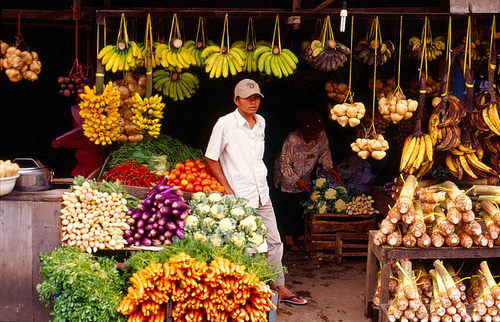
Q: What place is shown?
A: It is a market.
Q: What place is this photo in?
A: It is at the market.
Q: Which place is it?
A: It is a market.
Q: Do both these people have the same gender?
A: No, they are both male and female.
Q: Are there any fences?
A: No, there are no fences.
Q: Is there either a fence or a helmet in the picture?
A: No, there are no fences or helmets.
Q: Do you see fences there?
A: No, there are no fences.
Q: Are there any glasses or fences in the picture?
A: No, there are no fences or glasses.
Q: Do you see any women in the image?
A: Yes, there is a woman.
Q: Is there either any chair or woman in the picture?
A: Yes, there is a woman.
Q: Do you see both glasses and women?
A: No, there is a woman but no glasses.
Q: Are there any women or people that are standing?
A: Yes, the woman is standing.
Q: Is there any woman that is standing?
A: Yes, there is a woman that is standing.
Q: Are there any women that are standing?
A: Yes, there is a woman that is standing.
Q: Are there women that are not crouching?
A: Yes, there is a woman that is standing.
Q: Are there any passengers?
A: No, there are no passengers.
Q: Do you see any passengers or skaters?
A: No, there are no passengers or skaters.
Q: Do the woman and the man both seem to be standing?
A: Yes, both the woman and the man are standing.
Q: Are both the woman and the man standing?
A: Yes, both the woman and the man are standing.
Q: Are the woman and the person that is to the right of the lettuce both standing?
A: Yes, both the woman and the man are standing.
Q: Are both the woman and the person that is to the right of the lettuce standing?
A: Yes, both the woman and the man are standing.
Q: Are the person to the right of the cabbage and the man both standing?
A: Yes, both the woman and the man are standing.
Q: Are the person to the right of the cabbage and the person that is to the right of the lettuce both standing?
A: Yes, both the woman and the man are standing.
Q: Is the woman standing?
A: Yes, the woman is standing.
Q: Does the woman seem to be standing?
A: Yes, the woman is standing.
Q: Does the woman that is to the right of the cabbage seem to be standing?
A: Yes, the woman is standing.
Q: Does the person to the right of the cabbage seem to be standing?
A: Yes, the woman is standing.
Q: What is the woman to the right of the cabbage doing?
A: The woman is standing.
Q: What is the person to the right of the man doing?
A: The woman is standing.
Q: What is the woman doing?
A: The woman is standing.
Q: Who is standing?
A: The woman is standing.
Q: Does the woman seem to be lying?
A: No, the woman is standing.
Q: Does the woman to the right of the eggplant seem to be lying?
A: No, the woman is standing.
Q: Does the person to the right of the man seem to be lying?
A: No, the woman is standing.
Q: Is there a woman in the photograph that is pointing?
A: No, there is a woman but she is standing.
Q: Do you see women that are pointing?
A: No, there is a woman but she is standing.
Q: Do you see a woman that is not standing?
A: No, there is a woman but she is standing.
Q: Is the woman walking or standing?
A: The woman is standing.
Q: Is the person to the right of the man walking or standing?
A: The woman is standing.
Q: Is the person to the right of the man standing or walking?
A: The woman is standing.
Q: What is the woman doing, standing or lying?
A: The woman is standing.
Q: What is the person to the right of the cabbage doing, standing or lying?
A: The woman is standing.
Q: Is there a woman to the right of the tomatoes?
A: Yes, there is a woman to the right of the tomatoes.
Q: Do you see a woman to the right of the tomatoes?
A: Yes, there is a woman to the right of the tomatoes.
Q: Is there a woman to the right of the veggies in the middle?
A: Yes, there is a woman to the right of the tomatoes.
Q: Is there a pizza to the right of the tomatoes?
A: No, there is a woman to the right of the tomatoes.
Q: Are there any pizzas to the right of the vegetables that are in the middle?
A: No, there is a woman to the right of the tomatoes.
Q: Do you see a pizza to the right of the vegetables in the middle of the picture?
A: No, there is a woman to the right of the tomatoes.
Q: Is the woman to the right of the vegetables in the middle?
A: Yes, the woman is to the right of the tomatoes.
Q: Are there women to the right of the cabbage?
A: Yes, there is a woman to the right of the cabbage.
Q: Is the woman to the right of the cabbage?
A: Yes, the woman is to the right of the cabbage.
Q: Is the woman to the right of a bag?
A: No, the woman is to the right of the cabbage.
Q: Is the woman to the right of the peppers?
A: Yes, the woman is to the right of the peppers.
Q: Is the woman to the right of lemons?
A: No, the woman is to the right of the peppers.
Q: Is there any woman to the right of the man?
A: Yes, there is a woman to the right of the man.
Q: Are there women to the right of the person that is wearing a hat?
A: Yes, there is a woman to the right of the man.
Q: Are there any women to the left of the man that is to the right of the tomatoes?
A: No, the woman is to the right of the man.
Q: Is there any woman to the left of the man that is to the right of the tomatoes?
A: No, the woman is to the right of the man.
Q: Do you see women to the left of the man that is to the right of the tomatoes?
A: No, the woman is to the right of the man.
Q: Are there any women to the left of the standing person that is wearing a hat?
A: No, the woman is to the right of the man.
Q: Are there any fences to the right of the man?
A: No, there is a woman to the right of the man.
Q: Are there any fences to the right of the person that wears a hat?
A: No, there is a woman to the right of the man.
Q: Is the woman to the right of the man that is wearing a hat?
A: Yes, the woman is to the right of the man.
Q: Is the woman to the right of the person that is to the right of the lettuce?
A: Yes, the woman is to the right of the man.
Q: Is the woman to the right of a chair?
A: No, the woman is to the right of the man.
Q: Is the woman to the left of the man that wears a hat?
A: No, the woman is to the right of the man.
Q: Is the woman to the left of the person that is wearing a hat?
A: No, the woman is to the right of the man.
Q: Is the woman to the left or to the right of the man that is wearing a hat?
A: The woman is to the right of the man.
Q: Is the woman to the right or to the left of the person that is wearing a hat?
A: The woman is to the right of the man.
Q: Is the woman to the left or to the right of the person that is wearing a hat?
A: The woman is to the right of the man.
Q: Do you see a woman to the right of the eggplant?
A: Yes, there is a woman to the right of the eggplant.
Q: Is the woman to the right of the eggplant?
A: Yes, the woman is to the right of the eggplant.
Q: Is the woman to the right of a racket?
A: No, the woman is to the right of the eggplant.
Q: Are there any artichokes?
A: No, there are no artichokes.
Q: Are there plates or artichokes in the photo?
A: No, there are no artichokes or plates.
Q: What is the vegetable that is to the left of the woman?
A: The vegetable is a cabbage.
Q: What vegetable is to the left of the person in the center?
A: The vegetable is a cabbage.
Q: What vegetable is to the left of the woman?
A: The vegetable is a cabbage.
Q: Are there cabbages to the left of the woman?
A: Yes, there is a cabbage to the left of the woman.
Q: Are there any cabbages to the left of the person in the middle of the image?
A: Yes, there is a cabbage to the left of the woman.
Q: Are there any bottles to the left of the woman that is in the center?
A: No, there is a cabbage to the left of the woman.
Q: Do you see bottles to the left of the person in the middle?
A: No, there is a cabbage to the left of the woman.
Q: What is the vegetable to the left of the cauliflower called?
A: The vegetable is a cabbage.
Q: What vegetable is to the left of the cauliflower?
A: The vegetable is a cabbage.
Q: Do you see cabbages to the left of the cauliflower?
A: Yes, there is a cabbage to the left of the cauliflower.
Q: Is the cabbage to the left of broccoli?
A: No, the cabbage is to the left of the cauliflower.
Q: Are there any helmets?
A: No, there are no helmets.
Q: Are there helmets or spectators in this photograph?
A: No, there are no helmets or spectators.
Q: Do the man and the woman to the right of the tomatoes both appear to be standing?
A: Yes, both the man and the woman are standing.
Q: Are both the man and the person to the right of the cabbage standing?
A: Yes, both the man and the woman are standing.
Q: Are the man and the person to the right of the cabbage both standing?
A: Yes, both the man and the woman are standing.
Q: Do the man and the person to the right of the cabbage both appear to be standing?
A: Yes, both the man and the woman are standing.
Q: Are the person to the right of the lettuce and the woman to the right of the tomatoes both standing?
A: Yes, both the man and the woman are standing.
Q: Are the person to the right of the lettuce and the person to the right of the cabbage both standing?
A: Yes, both the man and the woman are standing.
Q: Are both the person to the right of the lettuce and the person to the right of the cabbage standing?
A: Yes, both the man and the woman are standing.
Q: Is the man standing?
A: Yes, the man is standing.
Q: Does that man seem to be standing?
A: Yes, the man is standing.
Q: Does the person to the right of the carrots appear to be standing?
A: Yes, the man is standing.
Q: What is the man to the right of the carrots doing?
A: The man is standing.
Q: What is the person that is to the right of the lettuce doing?
A: The man is standing.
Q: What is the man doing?
A: The man is standing.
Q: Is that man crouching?
A: No, the man is standing.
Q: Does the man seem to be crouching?
A: No, the man is standing.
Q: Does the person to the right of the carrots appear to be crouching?
A: No, the man is standing.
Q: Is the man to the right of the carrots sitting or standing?
A: The man is standing.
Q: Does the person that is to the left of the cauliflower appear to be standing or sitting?
A: The man is standing.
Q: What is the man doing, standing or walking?
A: The man is standing.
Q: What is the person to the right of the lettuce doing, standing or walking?
A: The man is standing.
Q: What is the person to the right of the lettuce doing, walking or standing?
A: The man is standing.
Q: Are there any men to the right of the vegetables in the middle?
A: Yes, there is a man to the right of the tomatoes.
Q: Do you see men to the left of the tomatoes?
A: No, the man is to the right of the tomatoes.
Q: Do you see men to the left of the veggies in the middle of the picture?
A: No, the man is to the right of the tomatoes.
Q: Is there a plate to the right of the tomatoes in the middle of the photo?
A: No, there is a man to the right of the tomatoes.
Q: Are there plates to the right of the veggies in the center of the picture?
A: No, there is a man to the right of the tomatoes.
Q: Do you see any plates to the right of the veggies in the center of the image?
A: No, there is a man to the right of the tomatoes.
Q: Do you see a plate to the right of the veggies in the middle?
A: No, there is a man to the right of the tomatoes.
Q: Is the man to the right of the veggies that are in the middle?
A: Yes, the man is to the right of the tomatoes.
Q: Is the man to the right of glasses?
A: No, the man is to the right of the tomatoes.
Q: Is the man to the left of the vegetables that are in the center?
A: No, the man is to the right of the tomatoes.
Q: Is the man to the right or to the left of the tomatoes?
A: The man is to the right of the tomatoes.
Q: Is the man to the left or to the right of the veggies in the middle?
A: The man is to the right of the tomatoes.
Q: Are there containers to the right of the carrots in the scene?
A: No, there is a man to the right of the carrots.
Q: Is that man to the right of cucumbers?
A: No, the man is to the right of the carrots.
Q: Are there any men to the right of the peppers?
A: Yes, there is a man to the right of the peppers.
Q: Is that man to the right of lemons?
A: No, the man is to the right of the peppers.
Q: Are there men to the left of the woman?
A: Yes, there is a man to the left of the woman.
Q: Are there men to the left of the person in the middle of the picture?
A: Yes, there is a man to the left of the woman.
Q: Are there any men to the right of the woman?
A: No, the man is to the left of the woman.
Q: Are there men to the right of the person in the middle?
A: No, the man is to the left of the woman.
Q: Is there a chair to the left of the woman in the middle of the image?
A: No, there is a man to the left of the woman.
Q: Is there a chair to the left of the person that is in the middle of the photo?
A: No, there is a man to the left of the woman.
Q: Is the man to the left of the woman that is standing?
A: Yes, the man is to the left of the woman.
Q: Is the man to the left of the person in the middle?
A: Yes, the man is to the left of the woman.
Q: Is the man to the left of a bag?
A: No, the man is to the left of the woman.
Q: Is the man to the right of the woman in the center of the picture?
A: No, the man is to the left of the woman.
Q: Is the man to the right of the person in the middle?
A: No, the man is to the left of the woman.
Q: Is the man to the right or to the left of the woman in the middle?
A: The man is to the left of the woman.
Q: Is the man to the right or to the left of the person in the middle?
A: The man is to the left of the woman.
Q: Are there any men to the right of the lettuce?
A: Yes, there is a man to the right of the lettuce.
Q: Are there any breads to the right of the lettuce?
A: No, there is a man to the right of the lettuce.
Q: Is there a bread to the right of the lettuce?
A: No, there is a man to the right of the lettuce.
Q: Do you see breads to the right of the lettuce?
A: No, there is a man to the right of the lettuce.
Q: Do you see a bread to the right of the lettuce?
A: No, there is a man to the right of the lettuce.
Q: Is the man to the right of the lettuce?
A: Yes, the man is to the right of the lettuce.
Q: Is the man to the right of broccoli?
A: No, the man is to the right of the lettuce.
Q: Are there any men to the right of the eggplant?
A: Yes, there is a man to the right of the eggplant.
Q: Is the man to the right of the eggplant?
A: Yes, the man is to the right of the eggplant.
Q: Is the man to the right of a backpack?
A: No, the man is to the right of the eggplant.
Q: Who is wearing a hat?
A: The man is wearing a hat.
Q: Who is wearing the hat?
A: The man is wearing a hat.